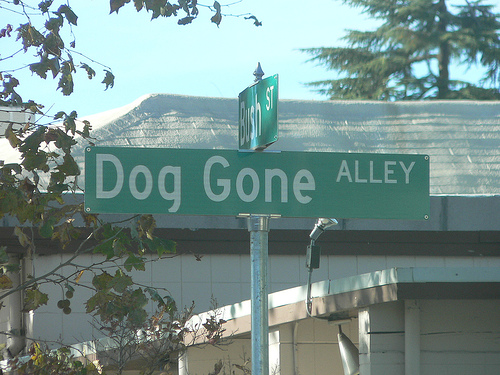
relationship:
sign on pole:
[77, 143, 437, 231] [240, 212, 271, 372]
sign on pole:
[223, 70, 290, 147] [240, 212, 271, 372]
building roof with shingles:
[46, 127, 443, 231] [116, 102, 228, 139]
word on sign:
[90, 153, 180, 215] [82, 146, 429, 221]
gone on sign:
[193, 152, 319, 212] [73, 150, 432, 207]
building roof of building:
[46, 92, 497, 194] [0, 91, 496, 374]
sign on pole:
[84, 146, 431, 222] [241, 212, 287, 372]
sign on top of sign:
[236, 72, 279, 151] [82, 146, 429, 221]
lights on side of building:
[300, 219, 361, 374] [19, 206, 499, 366]